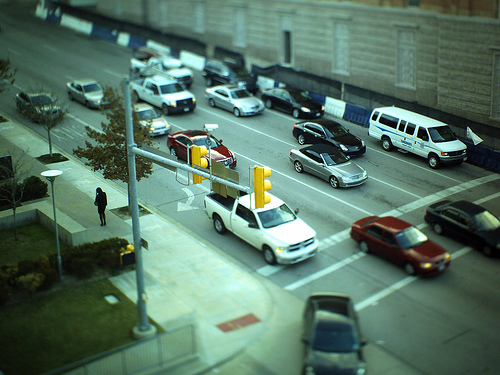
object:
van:
[367, 106, 468, 169]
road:
[0, 0, 500, 375]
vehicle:
[167, 129, 238, 170]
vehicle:
[14, 91, 63, 126]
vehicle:
[66, 77, 116, 109]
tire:
[357, 240, 370, 253]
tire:
[329, 175, 339, 188]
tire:
[294, 160, 303, 174]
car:
[289, 144, 368, 189]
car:
[203, 83, 266, 118]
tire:
[208, 98, 215, 108]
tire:
[233, 107, 241, 117]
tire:
[432, 222, 445, 235]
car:
[424, 199, 499, 259]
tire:
[482, 245, 493, 256]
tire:
[404, 262, 415, 275]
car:
[349, 214, 451, 278]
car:
[203, 191, 320, 266]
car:
[300, 293, 369, 374]